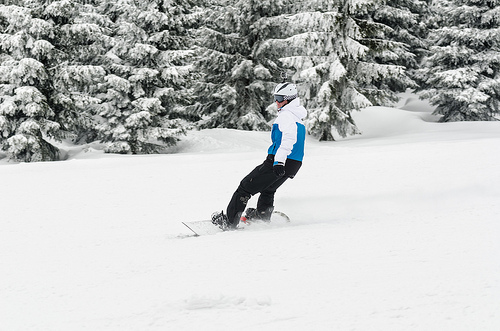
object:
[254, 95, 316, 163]
blue jacket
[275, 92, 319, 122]
hood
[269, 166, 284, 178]
gloves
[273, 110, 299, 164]
sleeve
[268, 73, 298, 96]
white hat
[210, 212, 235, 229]
shoe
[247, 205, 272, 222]
shoe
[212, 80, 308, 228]
man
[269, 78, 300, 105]
hat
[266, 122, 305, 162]
coat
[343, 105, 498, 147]
snow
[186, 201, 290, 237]
skate board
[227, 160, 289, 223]
black pants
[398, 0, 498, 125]
tree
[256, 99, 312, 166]
jacket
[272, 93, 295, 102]
goggles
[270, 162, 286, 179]
black mitten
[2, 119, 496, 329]
snow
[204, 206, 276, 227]
feet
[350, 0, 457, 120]
pine trees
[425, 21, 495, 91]
snow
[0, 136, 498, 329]
slope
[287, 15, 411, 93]
snow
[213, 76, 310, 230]
skateboarder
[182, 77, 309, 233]
skier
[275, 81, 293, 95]
stripe